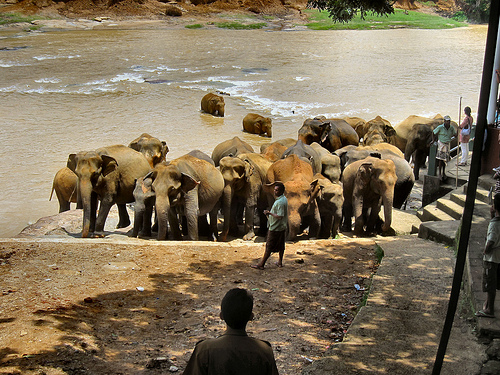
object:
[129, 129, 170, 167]
elephant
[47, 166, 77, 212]
elephant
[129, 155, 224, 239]
elephant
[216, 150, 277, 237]
elephant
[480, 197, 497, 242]
man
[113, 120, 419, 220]
elephants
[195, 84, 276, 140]
elephants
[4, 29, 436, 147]
river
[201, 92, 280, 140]
elephants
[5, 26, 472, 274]
river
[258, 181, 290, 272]
guy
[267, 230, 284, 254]
shorts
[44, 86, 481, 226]
elephants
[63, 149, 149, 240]
elephant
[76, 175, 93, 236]
trunk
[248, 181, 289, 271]
guy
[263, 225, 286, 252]
shorts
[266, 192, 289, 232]
polo shirt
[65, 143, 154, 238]
elephant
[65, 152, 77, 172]
ear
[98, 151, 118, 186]
ear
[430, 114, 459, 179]
guy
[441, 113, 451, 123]
hat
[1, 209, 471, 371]
river bank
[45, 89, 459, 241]
group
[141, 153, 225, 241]
elephant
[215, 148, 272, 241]
elephant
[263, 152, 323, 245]
elephant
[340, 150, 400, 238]
elephant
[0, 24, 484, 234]
river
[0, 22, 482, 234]
water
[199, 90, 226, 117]
elephant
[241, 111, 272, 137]
elephant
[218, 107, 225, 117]
trunk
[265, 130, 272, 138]
trunk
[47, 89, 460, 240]
herd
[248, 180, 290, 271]
man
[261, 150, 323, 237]
elephant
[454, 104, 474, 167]
woman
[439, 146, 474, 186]
dock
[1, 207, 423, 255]
water's edge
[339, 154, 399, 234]
elephant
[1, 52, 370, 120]
river rapid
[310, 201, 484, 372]
walkway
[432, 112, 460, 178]
man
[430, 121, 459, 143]
shirt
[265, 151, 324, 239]
elephant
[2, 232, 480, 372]
shadow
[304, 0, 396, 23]
tree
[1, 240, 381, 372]
beach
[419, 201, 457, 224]
step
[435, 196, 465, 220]
step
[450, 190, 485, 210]
step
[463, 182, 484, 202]
step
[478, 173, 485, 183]
step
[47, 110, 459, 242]
group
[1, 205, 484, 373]
shoreline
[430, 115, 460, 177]
person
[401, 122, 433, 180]
person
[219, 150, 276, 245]
elephant